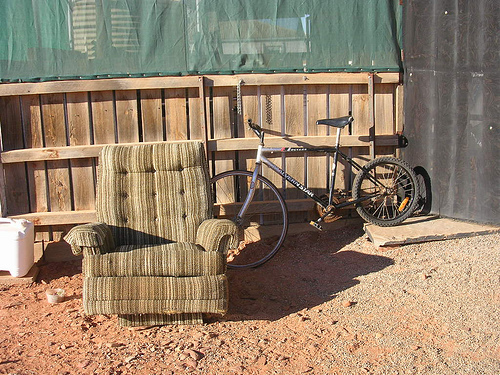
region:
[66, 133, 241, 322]
Old striped chair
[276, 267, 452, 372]
Two colors of dirt on the ground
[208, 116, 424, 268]
Bicycle with two different sized wheels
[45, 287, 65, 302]
Small plastic bowl on the ground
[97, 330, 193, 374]
Light red colored rocks and dirt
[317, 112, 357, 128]
Black bicycle seat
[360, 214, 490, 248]
Small concrete slab with bicycle tire on it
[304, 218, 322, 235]
Pedal on bicycle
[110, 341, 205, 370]
Rocks on the ground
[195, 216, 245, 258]
Arm of a striped chair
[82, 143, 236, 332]
yellow recliner sitting outside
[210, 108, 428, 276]
black and gray adults bike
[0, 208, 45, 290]
empty white jug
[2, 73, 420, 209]
wooden security fence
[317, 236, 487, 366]
red dirt in yard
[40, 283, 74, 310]
small white empty bowl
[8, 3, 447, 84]
green screen on top of security wall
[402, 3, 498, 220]
black tarp on side on outdoor fence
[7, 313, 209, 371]
red dirt and rocks in back yard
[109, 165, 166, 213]
buttons on back of yellow recliner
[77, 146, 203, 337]
this is a couch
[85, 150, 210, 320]
the couch is empty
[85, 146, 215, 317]
the couch is short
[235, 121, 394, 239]
a bicycle is beside the couch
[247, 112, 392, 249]
the bicycle is parked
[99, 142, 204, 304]
the couch is old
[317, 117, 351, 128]
the bicycle has black seat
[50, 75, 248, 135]
the fence is wooden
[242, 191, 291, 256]
the front tyre is big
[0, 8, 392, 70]
the net is green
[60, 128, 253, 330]
A LIVING ROOM CHAIR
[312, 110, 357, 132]
A BLACK BIKE SEAT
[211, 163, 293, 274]
A FRONT BIKE WHEEL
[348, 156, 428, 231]
A REAR BIKE WHEEL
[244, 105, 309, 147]
BIKE HANDLEBARS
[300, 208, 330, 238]
A BIKE PEDAL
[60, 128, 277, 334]
SUN SHINING ON A CHAIR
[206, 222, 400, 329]
A SHADOW ON THE GROUND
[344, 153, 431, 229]
BIKE WHEEL SPOKES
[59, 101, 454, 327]
A BIKE NEXT TO A CHAIR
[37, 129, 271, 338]
A chair is on the dirt.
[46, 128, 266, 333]
The chair is shabby looking.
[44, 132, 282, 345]
The chair is green.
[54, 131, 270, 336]
The chair is striped.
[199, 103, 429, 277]
A bicycle is behind the chair.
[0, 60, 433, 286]
A fence is behind the chair and bicycle.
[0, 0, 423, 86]
A tarp is attached to the fence.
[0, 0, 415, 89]
The tarp is green.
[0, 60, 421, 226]
The fence is wooden.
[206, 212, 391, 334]
The chair's shadow is on the dirt.